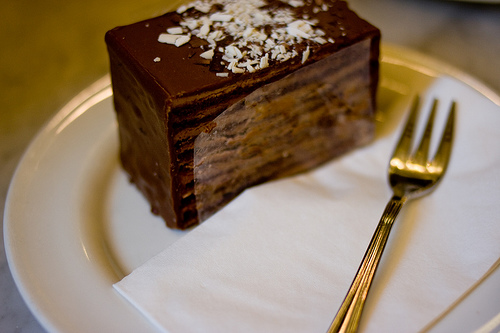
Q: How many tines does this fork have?
A: Three.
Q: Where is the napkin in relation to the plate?
A: On top.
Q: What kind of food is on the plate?
A: Cake.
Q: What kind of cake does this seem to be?
A: Chocolate.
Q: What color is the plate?
A: White.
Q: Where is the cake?
A: On the plate.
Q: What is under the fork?
A: The napkin.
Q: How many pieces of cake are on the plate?
A: One.